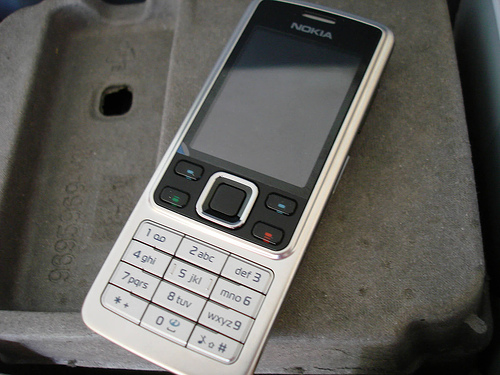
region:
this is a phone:
[126, 6, 319, 357]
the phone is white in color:
[230, 349, 275, 366]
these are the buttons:
[143, 238, 209, 325]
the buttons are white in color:
[187, 270, 223, 302]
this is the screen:
[249, 64, 300, 121]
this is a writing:
[281, 15, 327, 37]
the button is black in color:
[266, 192, 296, 212]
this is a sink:
[392, 91, 456, 245]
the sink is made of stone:
[397, 100, 455, 260]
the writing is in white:
[283, 18, 333, 42]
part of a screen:
[261, 108, 301, 152]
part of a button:
[210, 337, 242, 364]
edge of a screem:
[248, 158, 288, 213]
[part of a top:
[394, 259, 418, 284]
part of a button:
[200, 335, 225, 367]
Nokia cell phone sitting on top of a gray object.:
[12, 4, 489, 373]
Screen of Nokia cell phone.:
[159, 5, 411, 224]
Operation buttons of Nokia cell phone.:
[152, 137, 319, 252]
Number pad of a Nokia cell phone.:
[86, 204, 297, 373]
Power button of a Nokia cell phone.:
[244, 212, 296, 253]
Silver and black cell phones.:
[70, 1, 404, 366]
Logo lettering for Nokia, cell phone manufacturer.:
[267, 8, 360, 46]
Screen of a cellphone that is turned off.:
[158, 0, 358, 204]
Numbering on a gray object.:
[49, 136, 81, 296]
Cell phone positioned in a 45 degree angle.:
[11, 3, 477, 370]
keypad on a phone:
[119, 221, 264, 353]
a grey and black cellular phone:
[76, 5, 393, 373]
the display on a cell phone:
[202, 16, 344, 191]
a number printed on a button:
[140, 223, 157, 240]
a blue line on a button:
[174, 159, 201, 180]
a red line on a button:
[252, 220, 284, 248]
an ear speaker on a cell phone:
[302, 8, 340, 26]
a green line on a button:
[164, 189, 184, 206]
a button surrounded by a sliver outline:
[197, 170, 256, 227]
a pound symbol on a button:
[215, 338, 230, 355]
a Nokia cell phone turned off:
[66, 0, 403, 373]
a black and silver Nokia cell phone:
[84, 0, 395, 369]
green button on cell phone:
[161, 182, 188, 210]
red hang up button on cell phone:
[248, 222, 286, 242]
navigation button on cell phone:
[197, 172, 254, 225]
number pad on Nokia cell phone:
[95, 210, 273, 372]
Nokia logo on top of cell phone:
[284, 14, 341, 46]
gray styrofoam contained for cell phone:
[2, 7, 484, 359]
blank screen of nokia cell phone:
[177, 5, 373, 192]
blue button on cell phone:
[169, 156, 204, 181]